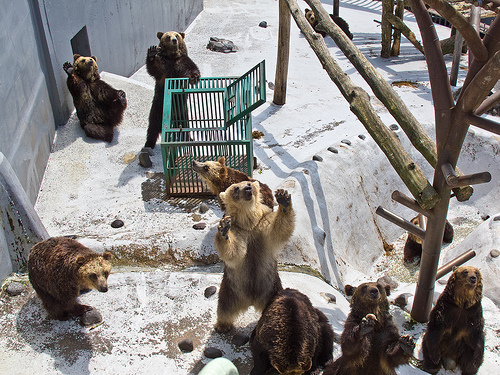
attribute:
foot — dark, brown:
[56, 57, 78, 83]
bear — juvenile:
[177, 151, 287, 208]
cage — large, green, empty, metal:
[156, 59, 267, 205]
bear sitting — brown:
[422, 273, 488, 375]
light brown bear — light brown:
[204, 177, 312, 329]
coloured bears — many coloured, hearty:
[50, 47, 478, 374]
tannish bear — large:
[204, 179, 305, 312]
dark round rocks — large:
[297, 128, 393, 171]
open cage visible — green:
[155, 79, 273, 194]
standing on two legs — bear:
[202, 177, 293, 325]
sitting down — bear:
[53, 43, 140, 154]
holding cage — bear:
[136, 32, 210, 95]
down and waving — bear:
[328, 262, 413, 372]